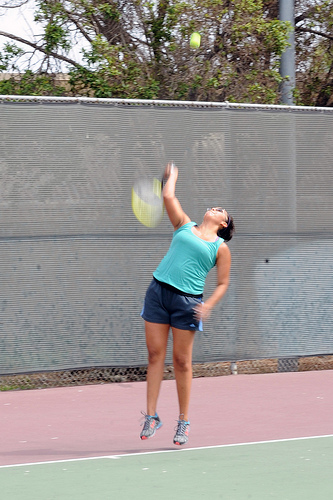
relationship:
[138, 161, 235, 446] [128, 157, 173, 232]
woman holding racket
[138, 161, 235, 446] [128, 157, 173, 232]
woman swinging racket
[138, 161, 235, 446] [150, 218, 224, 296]
woman wearing tank top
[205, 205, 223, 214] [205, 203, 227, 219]
glasses on front of face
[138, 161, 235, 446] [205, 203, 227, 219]
woman has face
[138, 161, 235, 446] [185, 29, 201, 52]
woman serving tennis ball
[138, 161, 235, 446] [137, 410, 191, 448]
woman wearing shoes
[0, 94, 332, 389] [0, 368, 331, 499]
fence next to court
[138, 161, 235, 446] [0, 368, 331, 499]
woman playing on court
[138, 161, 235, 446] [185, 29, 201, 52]
woman looking at tennis ball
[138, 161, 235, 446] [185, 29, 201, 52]
woman trying to hit tennis ball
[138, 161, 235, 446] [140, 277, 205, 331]
woman wearing shorts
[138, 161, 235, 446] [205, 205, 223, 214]
woman wearing glasses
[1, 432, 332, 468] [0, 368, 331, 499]
stripe on top of court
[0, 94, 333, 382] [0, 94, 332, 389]
fence on top of fence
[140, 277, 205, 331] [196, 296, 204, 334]
shorts have trim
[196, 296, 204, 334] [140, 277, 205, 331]
trim o side of shorts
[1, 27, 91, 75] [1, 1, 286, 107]
brach hanging from tree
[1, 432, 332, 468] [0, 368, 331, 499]
stripe along court